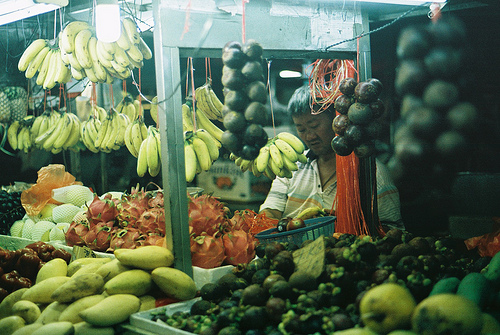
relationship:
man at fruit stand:
[291, 95, 330, 156] [23, 10, 481, 326]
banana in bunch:
[77, 50, 88, 58] [63, 43, 154, 79]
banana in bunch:
[49, 59, 52, 90] [63, 43, 154, 79]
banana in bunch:
[66, 27, 70, 48] [63, 43, 154, 79]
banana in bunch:
[26, 43, 39, 61] [63, 43, 154, 79]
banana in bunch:
[34, 53, 41, 71] [63, 43, 154, 79]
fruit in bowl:
[273, 214, 307, 229] [263, 218, 336, 245]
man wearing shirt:
[291, 95, 330, 156] [284, 178, 310, 208]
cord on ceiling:
[237, 1, 258, 40] [181, 2, 407, 10]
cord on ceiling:
[184, 4, 192, 40] [181, 2, 407, 10]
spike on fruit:
[208, 239, 218, 247] [92, 196, 112, 216]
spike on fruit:
[85, 201, 94, 216] [197, 201, 212, 219]